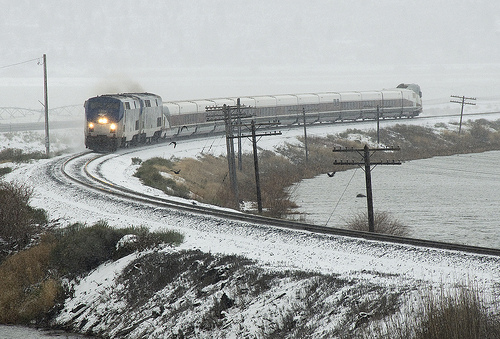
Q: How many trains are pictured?
A: 1.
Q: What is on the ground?
A: Snow.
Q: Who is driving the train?
A: Conductor.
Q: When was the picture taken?
A: Morning.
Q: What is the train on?
A: Tracks.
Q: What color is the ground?
A: White.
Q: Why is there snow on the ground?
A: Winter.